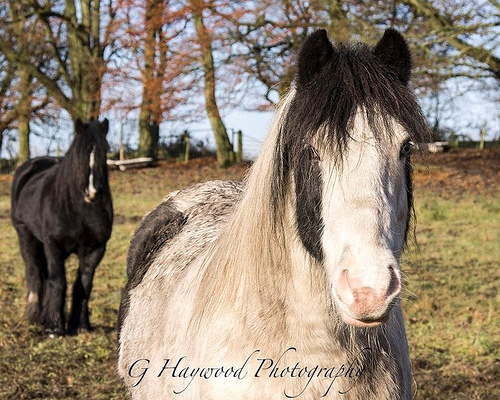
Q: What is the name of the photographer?
A: G Haywood.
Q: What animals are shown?
A: Horse.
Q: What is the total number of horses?
A: 2.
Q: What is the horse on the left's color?
A: Black.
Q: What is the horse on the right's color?
A: White.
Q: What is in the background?
A: Trees.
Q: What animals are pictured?
A: Horses.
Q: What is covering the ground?
A: Leaves.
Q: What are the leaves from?
A: Trees.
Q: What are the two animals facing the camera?
A: Horses.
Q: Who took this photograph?
A: G Haywood Photography.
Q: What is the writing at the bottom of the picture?
A: Photography company's logo.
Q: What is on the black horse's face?
A: White stripe.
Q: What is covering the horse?
A: Hair and fur.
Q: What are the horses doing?
A: Standing.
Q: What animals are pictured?
A: Horses.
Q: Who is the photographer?
A: G Haywood.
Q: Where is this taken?
A: A horse pasture.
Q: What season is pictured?
A: Maybe Autumn.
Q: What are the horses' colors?
A: White, black and gray.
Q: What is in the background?
A: Trees.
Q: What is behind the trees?
A: Fence.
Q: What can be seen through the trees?
A: Blue sky.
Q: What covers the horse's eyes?
A: It's mane.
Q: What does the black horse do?
A: Walks.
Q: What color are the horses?
A: Black and white.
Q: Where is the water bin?
A: By the fence.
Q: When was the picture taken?
A: Daytime.